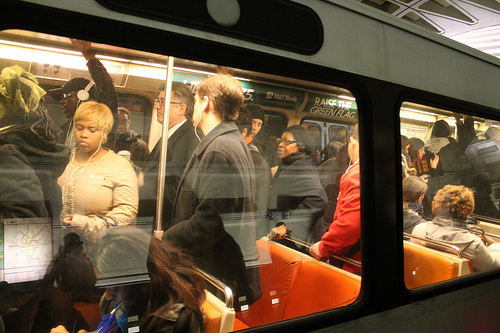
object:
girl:
[47, 225, 205, 333]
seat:
[231, 238, 363, 333]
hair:
[72, 101, 114, 142]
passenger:
[410, 184, 500, 271]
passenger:
[424, 119, 461, 171]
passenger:
[308, 122, 361, 276]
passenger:
[267, 125, 328, 261]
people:
[57, 101, 140, 243]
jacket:
[318, 159, 363, 277]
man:
[138, 82, 203, 237]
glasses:
[153, 98, 183, 105]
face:
[153, 91, 178, 123]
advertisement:
[303, 92, 358, 119]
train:
[0, 0, 500, 333]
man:
[161, 74, 255, 312]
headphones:
[194, 101, 203, 142]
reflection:
[31, 143, 340, 258]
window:
[0, 29, 365, 332]